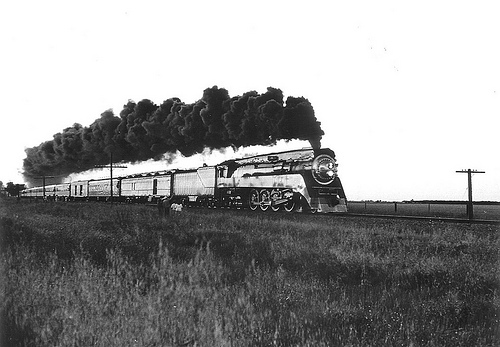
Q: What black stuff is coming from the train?
A: Smoke.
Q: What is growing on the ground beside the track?
A: Grass.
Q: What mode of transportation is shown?
A: Train.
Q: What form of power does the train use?
A: Steam.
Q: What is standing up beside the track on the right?
A: Power pole.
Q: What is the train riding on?
A: Rails.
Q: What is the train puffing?
A: Smoke.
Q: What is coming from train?
A: Smoke.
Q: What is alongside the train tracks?
A: Grassy field.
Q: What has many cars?
A: Train.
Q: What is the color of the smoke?
A: Black.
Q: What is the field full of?
A: Tall grass.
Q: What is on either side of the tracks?
A: Field.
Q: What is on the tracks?
A: Train.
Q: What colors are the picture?
A: Black and white.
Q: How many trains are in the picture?
A: One.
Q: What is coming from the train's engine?
A: Smoke.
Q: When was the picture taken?
A: Day time.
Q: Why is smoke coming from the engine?
A: It is moving.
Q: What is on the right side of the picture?
A: A transmission pole.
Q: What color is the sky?
A: White.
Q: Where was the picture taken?
A: The train tracks.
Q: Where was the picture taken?
A: Near a railroad.